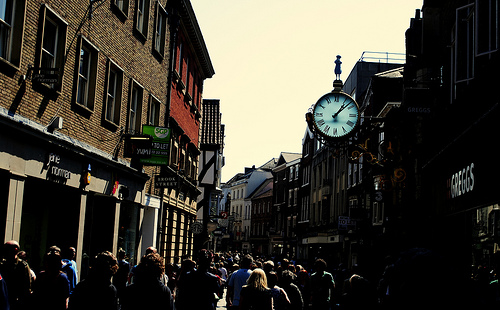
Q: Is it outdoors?
A: Yes, it is outdoors.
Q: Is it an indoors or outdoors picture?
A: It is outdoors.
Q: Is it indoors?
A: No, it is outdoors.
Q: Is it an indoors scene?
A: No, it is outdoors.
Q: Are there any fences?
A: No, there are no fences.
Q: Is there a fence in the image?
A: No, there are no fences.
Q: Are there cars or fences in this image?
A: No, there are no fences or cars.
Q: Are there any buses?
A: No, there are no buses.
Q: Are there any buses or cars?
A: No, there are no buses or cars.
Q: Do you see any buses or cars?
A: No, there are no buses or cars.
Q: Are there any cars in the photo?
A: No, there are no cars.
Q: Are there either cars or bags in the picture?
A: No, there are no cars or bags.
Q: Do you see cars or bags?
A: No, there are no cars or bags.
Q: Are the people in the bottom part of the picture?
A: Yes, the people are in the bottom of the image.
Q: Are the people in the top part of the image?
A: No, the people are in the bottom of the image.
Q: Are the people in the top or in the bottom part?
A: The people are in the bottom of the image.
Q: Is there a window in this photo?
A: Yes, there is a window.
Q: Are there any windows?
A: Yes, there is a window.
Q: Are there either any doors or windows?
A: Yes, there is a window.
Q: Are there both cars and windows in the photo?
A: No, there is a window but no cars.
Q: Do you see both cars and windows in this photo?
A: No, there is a window but no cars.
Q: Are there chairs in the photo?
A: No, there are no chairs.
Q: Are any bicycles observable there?
A: No, there are no bicycles.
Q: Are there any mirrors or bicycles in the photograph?
A: No, there are no bicycles or mirrors.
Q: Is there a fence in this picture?
A: No, there are no fences.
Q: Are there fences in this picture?
A: No, there are no fences.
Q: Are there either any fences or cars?
A: No, there are no fences or cars.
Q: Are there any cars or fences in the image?
A: No, there are no fences or cars.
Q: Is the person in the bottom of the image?
A: Yes, the person is in the bottom of the image.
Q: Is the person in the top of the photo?
A: No, the person is in the bottom of the image.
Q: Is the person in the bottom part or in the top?
A: The person is in the bottom of the image.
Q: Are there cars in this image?
A: No, there are no cars.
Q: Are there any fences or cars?
A: No, there are no cars or fences.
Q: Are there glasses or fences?
A: No, there are no fences or glasses.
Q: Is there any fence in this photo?
A: No, there are no fences.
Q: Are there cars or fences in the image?
A: No, there are no fences or cars.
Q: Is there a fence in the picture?
A: No, there are no fences.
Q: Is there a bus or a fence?
A: No, there are no fences or buses.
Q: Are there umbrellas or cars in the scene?
A: No, there are no cars or umbrellas.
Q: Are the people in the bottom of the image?
A: Yes, the people are in the bottom of the image.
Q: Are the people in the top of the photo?
A: No, the people are in the bottom of the image.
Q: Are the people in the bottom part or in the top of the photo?
A: The people are in the bottom of the image.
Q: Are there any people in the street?
A: Yes, there are people in the street.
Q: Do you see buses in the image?
A: No, there are no buses.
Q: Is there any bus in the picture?
A: No, there are no buses.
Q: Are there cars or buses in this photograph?
A: No, there are no buses or cars.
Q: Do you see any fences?
A: No, there are no fences.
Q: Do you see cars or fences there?
A: No, there are no fences or cars.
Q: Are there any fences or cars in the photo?
A: No, there are no fences or cars.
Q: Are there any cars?
A: No, there are no cars.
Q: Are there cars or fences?
A: No, there are no cars or fences.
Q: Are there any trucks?
A: No, there are no trucks.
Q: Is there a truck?
A: No, there are no trucks.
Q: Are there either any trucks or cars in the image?
A: No, there are no trucks or cars.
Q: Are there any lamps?
A: No, there are no lamps.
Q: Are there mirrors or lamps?
A: No, there are no lamps or mirrors.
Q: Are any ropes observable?
A: No, there are no ropes.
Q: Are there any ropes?
A: No, there are no ropes.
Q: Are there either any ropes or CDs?
A: No, there are no ropes or cds.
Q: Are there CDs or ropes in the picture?
A: No, there are no ropes or cds.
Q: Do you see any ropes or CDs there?
A: No, there are no ropes or cds.